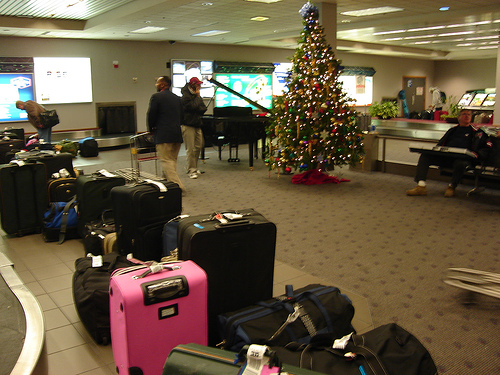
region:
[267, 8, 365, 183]
large christmas tree in the middle of the room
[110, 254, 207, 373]
a pink suitcase on the ground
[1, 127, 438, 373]
a line of luggage on the ground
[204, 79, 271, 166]
a black grand piano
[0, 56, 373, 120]
lighten bill boards on the wall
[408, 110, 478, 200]
man sitting down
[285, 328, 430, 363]
this is a bag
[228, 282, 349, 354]
this is a bag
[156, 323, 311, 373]
this is a bag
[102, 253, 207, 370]
this is a bag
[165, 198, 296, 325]
this is a bag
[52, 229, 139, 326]
this is a bag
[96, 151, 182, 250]
this is a bag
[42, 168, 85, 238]
this is a bag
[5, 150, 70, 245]
this is a bag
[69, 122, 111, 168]
this is a bag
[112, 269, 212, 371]
the suitcase is pink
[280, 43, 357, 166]
the Christmas tree is lit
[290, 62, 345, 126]
ornaments on the tree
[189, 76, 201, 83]
the hat is red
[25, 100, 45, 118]
the jacket is brown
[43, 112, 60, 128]
the bag is black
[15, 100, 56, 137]
the man is bent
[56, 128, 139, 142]
the conveyor belt is silver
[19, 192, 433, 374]
luggage on the floor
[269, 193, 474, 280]
the carpet is patterned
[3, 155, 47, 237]
luggage next to luggage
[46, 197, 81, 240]
luggage next to luggage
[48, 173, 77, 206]
luggage next to luggage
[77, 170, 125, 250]
luggage next to luggage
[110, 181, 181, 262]
luggage next to luggage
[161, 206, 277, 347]
luggage next to luggage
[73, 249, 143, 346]
luggage next to luggage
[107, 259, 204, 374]
luggage next to luggage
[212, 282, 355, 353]
luggage next to luggage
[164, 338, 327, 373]
luggage next to luggage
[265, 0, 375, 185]
Lit Christmas tree in the middle of the room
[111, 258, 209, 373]
Pink suitcase on the floor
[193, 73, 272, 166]
Piano to the left of the Christmas tree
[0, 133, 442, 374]
Luggage on the floor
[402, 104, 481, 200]
Man sitting in chair holding a box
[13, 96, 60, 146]
Man bent over looking at suitcase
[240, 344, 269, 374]
Tag on the suitcase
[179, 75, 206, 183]
Man in a red cap talking on a cell phone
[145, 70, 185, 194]
Man wearing a jacket and khaki pants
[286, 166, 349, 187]
Red cloth under tree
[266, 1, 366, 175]
a decorated and lit christmas tree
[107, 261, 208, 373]
a pink luggage suitcase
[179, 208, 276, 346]
a large black suitcase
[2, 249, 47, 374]
the corner of the luggage claim carousel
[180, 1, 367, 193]
man standing near a Christmas tree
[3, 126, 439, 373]
luggage lined up in a room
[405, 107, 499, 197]
man sitting on a bench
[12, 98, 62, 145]
person with a bag bending over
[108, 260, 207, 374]
lugge next to carousel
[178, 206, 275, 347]
lugge next to carousel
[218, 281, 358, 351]
lugge next to carousel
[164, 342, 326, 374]
lugge next to carousel